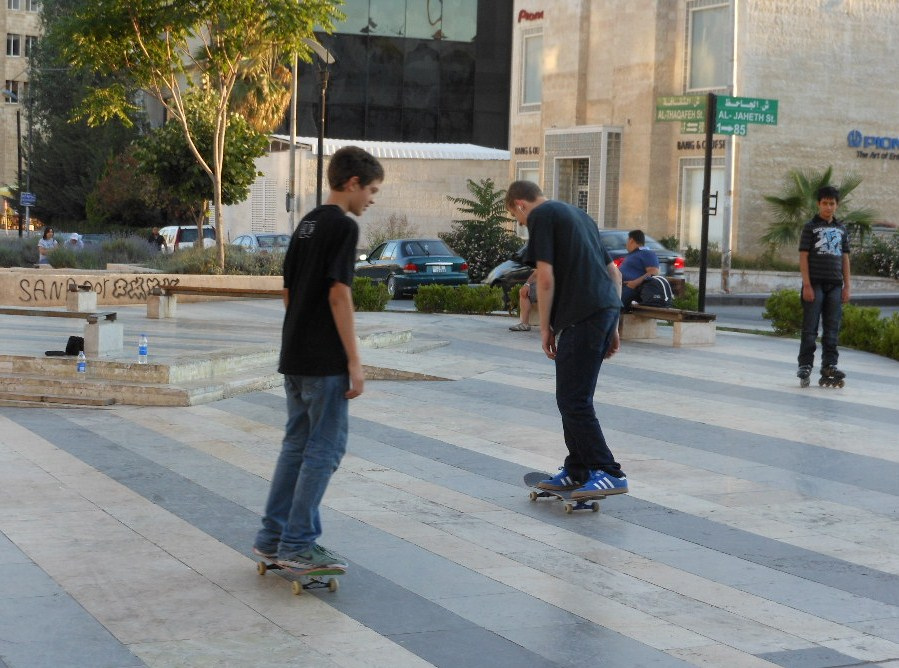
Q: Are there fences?
A: No, there are no fences.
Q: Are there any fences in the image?
A: No, there are no fences.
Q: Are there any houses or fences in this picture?
A: No, there are no fences or houses.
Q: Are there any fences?
A: No, there are no fences.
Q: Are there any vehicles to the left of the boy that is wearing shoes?
A: Yes, there are vehicles to the left of the boy.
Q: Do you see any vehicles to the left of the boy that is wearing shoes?
A: Yes, there are vehicles to the left of the boy.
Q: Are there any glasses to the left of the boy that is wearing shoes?
A: No, there are vehicles to the left of the boy.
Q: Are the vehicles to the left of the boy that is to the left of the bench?
A: Yes, the vehicles are to the left of the boy.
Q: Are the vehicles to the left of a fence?
A: No, the vehicles are to the left of the boy.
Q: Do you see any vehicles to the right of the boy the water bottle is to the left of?
A: Yes, there are vehicles to the right of the boy.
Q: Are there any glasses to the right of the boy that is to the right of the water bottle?
A: No, there are vehicles to the right of the boy.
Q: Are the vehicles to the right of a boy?
A: Yes, the vehicles are to the right of a boy.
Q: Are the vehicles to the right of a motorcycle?
A: No, the vehicles are to the right of a boy.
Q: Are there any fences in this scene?
A: No, there are no fences.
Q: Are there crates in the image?
A: No, there are no crates.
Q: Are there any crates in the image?
A: No, there are no crates.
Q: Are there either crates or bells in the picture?
A: No, there are no crates or bells.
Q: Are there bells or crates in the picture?
A: No, there are no crates or bells.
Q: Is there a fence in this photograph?
A: No, there are no fences.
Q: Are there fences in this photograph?
A: No, there are no fences.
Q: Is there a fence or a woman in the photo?
A: No, there are no fences or women.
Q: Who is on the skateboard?
A: The boy is on the skateboard.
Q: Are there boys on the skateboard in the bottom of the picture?
A: Yes, there is a boy on the skateboard.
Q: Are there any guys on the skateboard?
A: No, there is a boy on the skateboard.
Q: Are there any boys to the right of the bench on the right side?
A: Yes, there is a boy to the right of the bench.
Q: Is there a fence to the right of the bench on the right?
A: No, there is a boy to the right of the bench.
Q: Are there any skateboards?
A: Yes, there is a skateboard.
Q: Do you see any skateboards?
A: Yes, there is a skateboard.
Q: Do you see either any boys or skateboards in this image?
A: Yes, there is a skateboard.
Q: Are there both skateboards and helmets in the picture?
A: No, there is a skateboard but no helmets.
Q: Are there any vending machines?
A: No, there are no vending machines.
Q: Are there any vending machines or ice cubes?
A: No, there are no vending machines or ice cubes.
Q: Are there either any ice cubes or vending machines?
A: No, there are no vending machines or ice cubes.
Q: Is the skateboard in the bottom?
A: Yes, the skateboard is in the bottom of the image.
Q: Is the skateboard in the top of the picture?
A: No, the skateboard is in the bottom of the image.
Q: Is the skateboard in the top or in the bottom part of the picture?
A: The skateboard is in the bottom of the image.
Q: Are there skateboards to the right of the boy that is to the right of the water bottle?
A: Yes, there is a skateboard to the right of the boy.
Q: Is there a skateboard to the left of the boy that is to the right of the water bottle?
A: No, the skateboard is to the right of the boy.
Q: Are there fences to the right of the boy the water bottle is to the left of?
A: No, there is a skateboard to the right of the boy.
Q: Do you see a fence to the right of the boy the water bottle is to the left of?
A: No, there is a skateboard to the right of the boy.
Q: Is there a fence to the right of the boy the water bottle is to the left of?
A: No, there is a skateboard to the right of the boy.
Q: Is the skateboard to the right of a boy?
A: Yes, the skateboard is to the right of a boy.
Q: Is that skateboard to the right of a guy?
A: No, the skateboard is to the right of a boy.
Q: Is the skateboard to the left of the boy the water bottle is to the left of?
A: No, the skateboard is to the right of the boy.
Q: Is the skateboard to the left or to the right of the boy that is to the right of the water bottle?
A: The skateboard is to the right of the boy.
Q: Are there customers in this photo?
A: No, there are no customers.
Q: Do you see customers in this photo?
A: No, there are no customers.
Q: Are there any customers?
A: No, there are no customers.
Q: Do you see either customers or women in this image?
A: No, there are no customers or women.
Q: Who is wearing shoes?
A: The boy is wearing shoes.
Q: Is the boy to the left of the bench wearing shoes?
A: Yes, the boy is wearing shoes.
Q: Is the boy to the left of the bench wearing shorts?
A: No, the boy is wearing shoes.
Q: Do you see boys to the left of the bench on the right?
A: Yes, there is a boy to the left of the bench.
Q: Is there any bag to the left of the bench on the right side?
A: No, there is a boy to the left of the bench.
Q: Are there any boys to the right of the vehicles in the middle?
A: Yes, there is a boy to the right of the vehicles.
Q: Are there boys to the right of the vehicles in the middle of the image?
A: Yes, there is a boy to the right of the vehicles.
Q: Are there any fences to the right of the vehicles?
A: No, there is a boy to the right of the vehicles.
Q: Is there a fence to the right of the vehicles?
A: No, there is a boy to the right of the vehicles.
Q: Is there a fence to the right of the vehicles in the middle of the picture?
A: No, there is a boy to the right of the vehicles.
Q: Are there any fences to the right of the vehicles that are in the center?
A: No, there is a boy to the right of the vehicles.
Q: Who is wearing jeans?
A: The boy is wearing jeans.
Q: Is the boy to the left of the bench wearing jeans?
A: Yes, the boy is wearing jeans.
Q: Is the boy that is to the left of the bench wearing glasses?
A: No, the boy is wearing jeans.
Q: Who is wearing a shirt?
A: The boy is wearing a shirt.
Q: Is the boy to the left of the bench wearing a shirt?
A: Yes, the boy is wearing a shirt.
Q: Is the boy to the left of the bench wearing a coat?
A: No, the boy is wearing a shirt.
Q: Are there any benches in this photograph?
A: Yes, there is a bench.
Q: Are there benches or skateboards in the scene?
A: Yes, there is a bench.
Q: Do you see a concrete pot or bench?
A: Yes, there is a concrete bench.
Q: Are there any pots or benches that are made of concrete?
A: Yes, the bench is made of concrete.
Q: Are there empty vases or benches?
A: Yes, there is an empty bench.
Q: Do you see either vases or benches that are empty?
A: Yes, the bench is empty.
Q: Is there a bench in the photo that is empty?
A: Yes, there is an empty bench.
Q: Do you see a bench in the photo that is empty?
A: Yes, there is a bench that is empty.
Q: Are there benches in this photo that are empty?
A: Yes, there is a bench that is empty.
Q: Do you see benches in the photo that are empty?
A: Yes, there is a bench that is empty.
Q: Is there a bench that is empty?
A: Yes, there is a bench that is empty.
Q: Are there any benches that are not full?
A: Yes, there is a empty bench.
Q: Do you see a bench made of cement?
A: Yes, there is a bench that is made of cement.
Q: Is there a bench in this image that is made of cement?
A: Yes, there is a bench that is made of cement.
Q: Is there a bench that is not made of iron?
A: Yes, there is a bench that is made of cement.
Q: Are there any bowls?
A: No, there are no bowls.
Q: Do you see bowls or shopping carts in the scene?
A: No, there are no bowls or shopping carts.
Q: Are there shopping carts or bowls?
A: No, there are no bowls or shopping carts.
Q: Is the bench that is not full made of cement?
A: Yes, the bench is made of cement.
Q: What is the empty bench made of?
A: The bench is made of concrete.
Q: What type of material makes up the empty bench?
A: The bench is made of concrete.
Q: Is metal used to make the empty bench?
A: No, the bench is made of cement.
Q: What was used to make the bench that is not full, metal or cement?
A: The bench is made of cement.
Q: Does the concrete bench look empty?
A: Yes, the bench is empty.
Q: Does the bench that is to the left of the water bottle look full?
A: No, the bench is empty.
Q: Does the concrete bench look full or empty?
A: The bench is empty.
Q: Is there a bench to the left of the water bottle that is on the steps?
A: Yes, there is a bench to the left of the water bottle.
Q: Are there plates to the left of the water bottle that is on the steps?
A: No, there is a bench to the left of the water bottle.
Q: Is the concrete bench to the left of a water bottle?
A: Yes, the bench is to the left of a water bottle.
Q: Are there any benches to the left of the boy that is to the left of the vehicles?
A: Yes, there is a bench to the left of the boy.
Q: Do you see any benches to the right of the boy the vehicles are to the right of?
A: No, the bench is to the left of the boy.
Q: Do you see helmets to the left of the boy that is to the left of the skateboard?
A: No, there is a bench to the left of the boy.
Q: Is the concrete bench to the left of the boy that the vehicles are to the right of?
A: Yes, the bench is to the left of the boy.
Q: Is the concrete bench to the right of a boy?
A: No, the bench is to the left of a boy.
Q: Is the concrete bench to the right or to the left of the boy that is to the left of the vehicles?
A: The bench is to the left of the boy.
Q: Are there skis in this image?
A: No, there are no skis.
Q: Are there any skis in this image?
A: No, there are no skis.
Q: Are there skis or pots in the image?
A: No, there are no skis or pots.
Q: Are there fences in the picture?
A: No, there are no fences.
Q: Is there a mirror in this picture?
A: No, there are no mirrors.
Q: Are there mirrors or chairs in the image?
A: No, there are no mirrors or chairs.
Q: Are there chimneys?
A: No, there are no chimneys.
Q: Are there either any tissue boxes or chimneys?
A: No, there are no chimneys or tissue boxes.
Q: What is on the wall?
A: The graffiti is on the wall.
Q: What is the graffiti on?
A: The graffiti is on the wall.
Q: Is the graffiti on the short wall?
A: Yes, the graffiti is on the wall.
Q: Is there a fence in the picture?
A: No, there are no fences.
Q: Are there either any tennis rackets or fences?
A: No, there are no fences or tennis rackets.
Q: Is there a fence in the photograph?
A: No, there are no fences.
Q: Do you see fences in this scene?
A: No, there are no fences.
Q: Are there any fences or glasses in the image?
A: No, there are no fences or glasses.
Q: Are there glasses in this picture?
A: No, there are no glasses.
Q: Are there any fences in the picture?
A: No, there are no fences.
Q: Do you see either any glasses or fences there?
A: No, there are no fences or glasses.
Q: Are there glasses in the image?
A: No, there are no glasses.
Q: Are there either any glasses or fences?
A: No, there are no glasses or fences.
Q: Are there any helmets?
A: No, there are no helmets.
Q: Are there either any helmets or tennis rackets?
A: No, there are no helmets or tennis rackets.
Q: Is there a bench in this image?
A: Yes, there is a bench.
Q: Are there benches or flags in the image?
A: Yes, there is a bench.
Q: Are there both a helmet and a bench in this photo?
A: No, there is a bench but no helmets.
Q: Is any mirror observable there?
A: No, there are no mirrors.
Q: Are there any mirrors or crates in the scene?
A: No, there are no mirrors or crates.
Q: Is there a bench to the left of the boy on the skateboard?
A: Yes, there is a bench to the left of the boy.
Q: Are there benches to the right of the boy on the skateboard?
A: No, the bench is to the left of the boy.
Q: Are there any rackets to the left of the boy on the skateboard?
A: No, there is a bench to the left of the boy.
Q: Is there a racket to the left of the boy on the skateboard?
A: No, there is a bench to the left of the boy.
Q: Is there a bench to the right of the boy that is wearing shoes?
A: Yes, there is a bench to the right of the boy.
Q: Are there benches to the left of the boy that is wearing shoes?
A: No, the bench is to the right of the boy.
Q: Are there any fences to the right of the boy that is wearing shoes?
A: No, there is a bench to the right of the boy.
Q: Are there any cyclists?
A: No, there are no cyclists.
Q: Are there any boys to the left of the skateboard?
A: Yes, there is a boy to the left of the skateboard.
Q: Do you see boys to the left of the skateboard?
A: Yes, there is a boy to the left of the skateboard.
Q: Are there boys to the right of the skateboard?
A: No, the boy is to the left of the skateboard.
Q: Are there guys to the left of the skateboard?
A: No, there is a boy to the left of the skateboard.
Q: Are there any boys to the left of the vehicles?
A: Yes, there is a boy to the left of the vehicles.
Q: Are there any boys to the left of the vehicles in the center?
A: Yes, there is a boy to the left of the vehicles.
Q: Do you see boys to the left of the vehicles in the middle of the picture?
A: Yes, there is a boy to the left of the vehicles.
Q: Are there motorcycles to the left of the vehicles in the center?
A: No, there is a boy to the left of the vehicles.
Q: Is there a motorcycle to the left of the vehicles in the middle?
A: No, there is a boy to the left of the vehicles.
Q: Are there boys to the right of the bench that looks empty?
A: Yes, there is a boy to the right of the bench.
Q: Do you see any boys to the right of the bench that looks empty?
A: Yes, there is a boy to the right of the bench.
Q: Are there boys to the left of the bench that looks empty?
A: No, the boy is to the right of the bench.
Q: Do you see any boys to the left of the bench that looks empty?
A: No, the boy is to the right of the bench.